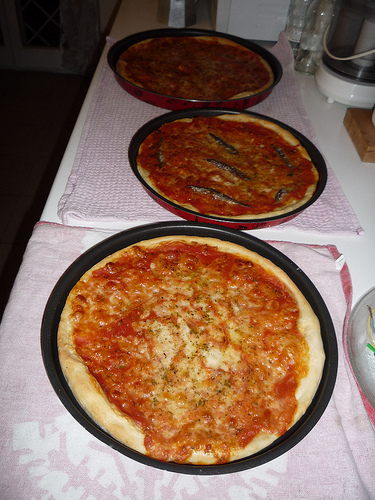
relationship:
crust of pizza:
[250, 112, 291, 137] [137, 113, 321, 209]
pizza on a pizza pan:
[138, 109, 319, 220] [126, 105, 329, 226]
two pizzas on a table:
[103, 21, 329, 224] [2, 2, 372, 497]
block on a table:
[335, 94, 371, 184] [5, 7, 374, 408]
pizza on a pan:
[138, 109, 319, 220] [87, 21, 343, 235]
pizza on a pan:
[139, 95, 351, 231] [95, 22, 307, 114]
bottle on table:
[291, 2, 333, 78] [101, 17, 355, 308]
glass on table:
[277, 0, 312, 54] [2, 2, 372, 497]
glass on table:
[291, 0, 336, 75] [2, 2, 372, 497]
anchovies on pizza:
[207, 130, 239, 155] [138, 109, 319, 220]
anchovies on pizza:
[206, 157, 249, 182] [138, 109, 319, 220]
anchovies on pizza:
[185, 184, 249, 208] [138, 109, 319, 220]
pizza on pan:
[138, 109, 319, 220] [126, 105, 326, 229]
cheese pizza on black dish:
[54, 237, 329, 466] [35, 219, 340, 482]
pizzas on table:
[109, 26, 297, 108] [2, 2, 372, 497]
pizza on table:
[138, 109, 319, 220] [2, 2, 372, 497]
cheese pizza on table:
[54, 237, 329, 466] [2, 2, 372, 497]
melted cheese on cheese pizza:
[94, 255, 290, 431] [54, 237, 329, 466]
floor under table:
[0, 18, 98, 326] [2, 2, 372, 497]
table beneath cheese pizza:
[2, 2, 372, 497] [54, 237, 329, 466]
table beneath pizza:
[2, 2, 372, 497] [136, 109, 320, 219]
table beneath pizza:
[2, 2, 372, 497] [117, 32, 276, 101]